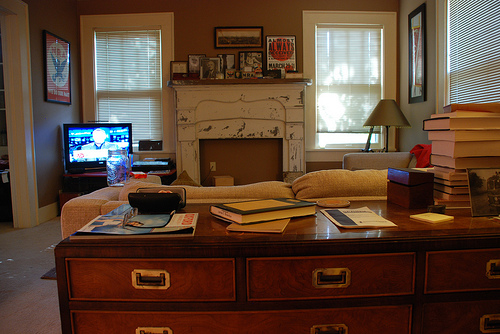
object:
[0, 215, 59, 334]
floor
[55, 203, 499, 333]
chest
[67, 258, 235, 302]
drawer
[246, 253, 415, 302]
drawer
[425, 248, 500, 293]
drawer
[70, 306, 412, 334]
drawer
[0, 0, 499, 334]
living room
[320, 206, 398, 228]
paper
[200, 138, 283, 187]
fireplace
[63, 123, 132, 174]
black tv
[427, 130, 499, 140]
books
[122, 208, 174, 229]
glasses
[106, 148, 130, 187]
mason jar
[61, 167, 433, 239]
couch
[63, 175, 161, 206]
arm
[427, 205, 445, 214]
pad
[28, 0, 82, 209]
wall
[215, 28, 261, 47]
photograph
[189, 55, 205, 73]
photograph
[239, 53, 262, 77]
photograph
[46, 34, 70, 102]
poster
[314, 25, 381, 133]
blinds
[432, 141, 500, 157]
books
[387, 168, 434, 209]
box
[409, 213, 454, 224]
cards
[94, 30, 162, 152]
window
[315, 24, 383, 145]
window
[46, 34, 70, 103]
picture frame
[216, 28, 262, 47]
picture frame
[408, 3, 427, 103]
picture frame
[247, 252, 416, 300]
board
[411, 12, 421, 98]
painting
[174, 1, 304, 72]
wall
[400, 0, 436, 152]
wall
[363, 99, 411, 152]
lamp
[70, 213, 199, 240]
book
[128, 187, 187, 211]
black case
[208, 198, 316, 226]
book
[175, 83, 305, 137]
mantle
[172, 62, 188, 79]
photos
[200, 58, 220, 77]
photos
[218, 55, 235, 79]
photos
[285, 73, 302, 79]
knickknacks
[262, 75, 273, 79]
knickknacks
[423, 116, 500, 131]
books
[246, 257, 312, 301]
part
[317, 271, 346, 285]
part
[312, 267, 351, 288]
handle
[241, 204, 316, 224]
edge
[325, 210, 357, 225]
part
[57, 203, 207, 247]
part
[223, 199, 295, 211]
part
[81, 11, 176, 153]
frame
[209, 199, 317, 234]
pile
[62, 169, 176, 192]
table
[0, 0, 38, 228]
frame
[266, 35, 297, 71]
frame